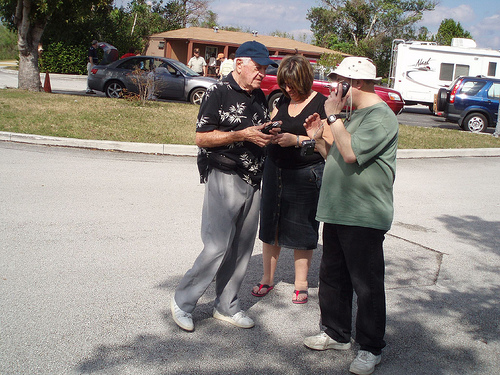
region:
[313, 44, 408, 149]
a man on cell phone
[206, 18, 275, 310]
a man wearing a blue hat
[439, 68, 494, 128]
a blue car in background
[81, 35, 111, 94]
a man behind a car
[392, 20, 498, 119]
a rv in the distance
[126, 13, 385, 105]
a building behind the people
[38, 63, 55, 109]
an orange cone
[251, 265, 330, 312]
sandals on feet of woman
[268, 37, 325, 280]
a woman in black dress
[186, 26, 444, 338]
3 people in the fore ground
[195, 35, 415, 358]
three people standing on the pavement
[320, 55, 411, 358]
the man holding the cellphone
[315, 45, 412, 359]
the man talking on the cellphone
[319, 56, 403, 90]
the man wearing the white hat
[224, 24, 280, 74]
the man wearing the blue hat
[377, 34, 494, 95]
the recreational vehicle beside the tree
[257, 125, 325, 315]
the woman wearing pink sandals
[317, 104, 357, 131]
the watch on the wrist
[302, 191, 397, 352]
the man wearing black pants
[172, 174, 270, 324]
the man wearing gray pants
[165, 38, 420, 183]
people on the street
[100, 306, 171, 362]
shadow on the ground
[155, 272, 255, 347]
shoes on man's feet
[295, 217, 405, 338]
pants on the man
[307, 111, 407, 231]
green shirt on man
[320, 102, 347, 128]
watch around man's wrist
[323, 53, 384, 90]
hat on man's head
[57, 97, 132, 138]
grass next to road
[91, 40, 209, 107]
car next to grass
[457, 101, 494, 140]
tire of the car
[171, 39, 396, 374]
A group of people standing together.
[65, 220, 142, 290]
Part of the road.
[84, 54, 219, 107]
A small grey car.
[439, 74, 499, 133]
Part of a blue car.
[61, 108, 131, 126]
Part of the grass.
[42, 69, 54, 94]
An orange cone.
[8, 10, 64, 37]
Part of a tree.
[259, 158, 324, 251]
A denim skirt.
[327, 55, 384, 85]
The man's white hat.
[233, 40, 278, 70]
A blue baseball cap.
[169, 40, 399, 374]
group of people is interacting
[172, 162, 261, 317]
older man is wearing grey pants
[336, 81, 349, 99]
man holding up cell phone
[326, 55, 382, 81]
man wearing white hat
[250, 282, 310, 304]
woman wearing black and pink sandals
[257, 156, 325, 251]
woman wearing denim skirt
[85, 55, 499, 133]
cars parked behind group of people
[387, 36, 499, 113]
white rv behind cars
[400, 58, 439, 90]
logo on side of rv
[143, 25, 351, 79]
brown house behind cars